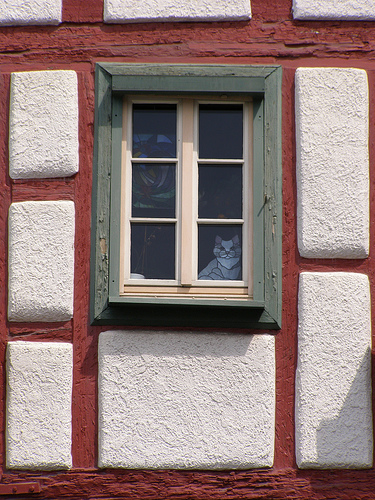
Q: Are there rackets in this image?
A: No, there are no rackets.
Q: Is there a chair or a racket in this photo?
A: No, there are no rackets or chairs.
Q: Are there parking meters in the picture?
A: No, there are no parking meters.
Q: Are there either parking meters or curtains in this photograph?
A: No, there are no parking meters or curtains.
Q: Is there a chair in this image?
A: No, there are no chairs.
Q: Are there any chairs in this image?
A: No, there are no chairs.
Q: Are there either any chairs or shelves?
A: No, there are no chairs or shelves.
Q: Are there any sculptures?
A: No, there are no sculptures.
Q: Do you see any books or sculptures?
A: No, there are no sculptures or books.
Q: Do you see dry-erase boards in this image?
A: No, there are no dry-erase boards.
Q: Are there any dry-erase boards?
A: No, there are no dry-erase boards.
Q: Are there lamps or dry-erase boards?
A: No, there are no dry-erase boards or lamps.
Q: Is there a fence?
A: No, there are no fences.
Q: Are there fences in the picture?
A: No, there are no fences.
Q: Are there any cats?
A: Yes, there is a cat.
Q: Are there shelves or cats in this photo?
A: Yes, there is a cat.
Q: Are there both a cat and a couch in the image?
A: No, there is a cat but no couches.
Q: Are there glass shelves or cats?
A: Yes, there is a glass cat.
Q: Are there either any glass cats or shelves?
A: Yes, there is a glass cat.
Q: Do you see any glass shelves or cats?
A: Yes, there is a glass cat.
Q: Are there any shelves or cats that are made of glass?
A: Yes, the cat is made of glass.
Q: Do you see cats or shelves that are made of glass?
A: Yes, the cat is made of glass.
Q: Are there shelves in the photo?
A: No, there are no shelves.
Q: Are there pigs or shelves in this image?
A: No, there are no shelves or pigs.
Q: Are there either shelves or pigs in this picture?
A: No, there are no shelves or pigs.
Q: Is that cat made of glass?
A: Yes, the cat is made of glass.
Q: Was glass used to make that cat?
A: Yes, the cat is made of glass.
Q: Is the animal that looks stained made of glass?
A: Yes, the cat is made of glass.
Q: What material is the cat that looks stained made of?
A: The cat is made of glass.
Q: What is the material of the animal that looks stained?
A: The cat is made of glass.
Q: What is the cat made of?
A: The cat is made of glass.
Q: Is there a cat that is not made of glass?
A: No, there is a cat but it is made of glass.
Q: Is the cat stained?
A: Yes, the cat is stained.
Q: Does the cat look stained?
A: Yes, the cat is stained.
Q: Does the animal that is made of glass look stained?
A: Yes, the cat is stained.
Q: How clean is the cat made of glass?
A: The cat is stained.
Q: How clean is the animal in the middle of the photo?
A: The cat is stained.